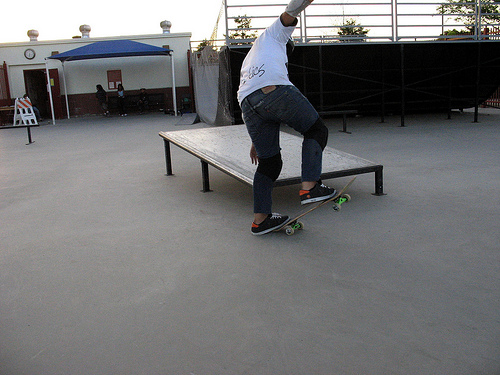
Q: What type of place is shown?
A: It is a park.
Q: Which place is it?
A: It is a park.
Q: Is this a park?
A: Yes, it is a park.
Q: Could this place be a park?
A: Yes, it is a park.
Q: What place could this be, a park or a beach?
A: It is a park.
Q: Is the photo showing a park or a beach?
A: It is showing a park.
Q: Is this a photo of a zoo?
A: No, the picture is showing a park.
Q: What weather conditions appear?
A: It is cloudy.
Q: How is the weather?
A: It is cloudy.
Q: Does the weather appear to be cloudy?
A: Yes, it is cloudy.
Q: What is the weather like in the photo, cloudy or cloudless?
A: It is cloudy.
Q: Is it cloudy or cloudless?
A: It is cloudy.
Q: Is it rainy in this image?
A: No, it is cloudy.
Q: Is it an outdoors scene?
A: Yes, it is outdoors.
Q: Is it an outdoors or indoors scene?
A: It is outdoors.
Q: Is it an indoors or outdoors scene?
A: It is outdoors.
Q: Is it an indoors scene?
A: No, it is outdoors.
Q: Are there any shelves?
A: No, there are no shelves.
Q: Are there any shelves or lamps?
A: No, there are no shelves or lamps.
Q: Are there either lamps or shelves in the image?
A: No, there are no shelves or lamps.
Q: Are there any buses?
A: No, there are no buses.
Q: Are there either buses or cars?
A: No, there are no buses or cars.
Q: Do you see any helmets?
A: No, there are no helmets.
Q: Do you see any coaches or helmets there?
A: No, there are no helmets or coaches.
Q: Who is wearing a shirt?
A: The man is wearing a shirt.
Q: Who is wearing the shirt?
A: The man is wearing a shirt.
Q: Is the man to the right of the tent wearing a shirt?
A: Yes, the man is wearing a shirt.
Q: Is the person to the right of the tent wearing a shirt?
A: Yes, the man is wearing a shirt.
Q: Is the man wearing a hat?
A: No, the man is wearing a shirt.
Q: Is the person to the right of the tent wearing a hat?
A: No, the man is wearing a shirt.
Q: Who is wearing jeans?
A: The man is wearing jeans.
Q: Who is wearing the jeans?
A: The man is wearing jeans.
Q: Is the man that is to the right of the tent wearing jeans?
A: Yes, the man is wearing jeans.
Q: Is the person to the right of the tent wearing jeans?
A: Yes, the man is wearing jeans.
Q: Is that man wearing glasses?
A: No, the man is wearing jeans.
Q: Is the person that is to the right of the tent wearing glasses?
A: No, the man is wearing jeans.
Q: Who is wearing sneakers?
A: The man is wearing sneakers.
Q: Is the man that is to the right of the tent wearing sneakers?
A: Yes, the man is wearing sneakers.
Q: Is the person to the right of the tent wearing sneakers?
A: Yes, the man is wearing sneakers.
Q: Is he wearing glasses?
A: No, the man is wearing sneakers.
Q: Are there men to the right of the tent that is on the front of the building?
A: Yes, there is a man to the right of the tent.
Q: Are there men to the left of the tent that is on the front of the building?
A: No, the man is to the right of the tent.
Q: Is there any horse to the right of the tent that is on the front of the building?
A: No, there is a man to the right of the tent.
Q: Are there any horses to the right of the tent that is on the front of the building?
A: No, there is a man to the right of the tent.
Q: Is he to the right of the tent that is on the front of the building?
A: Yes, the man is to the right of the tent.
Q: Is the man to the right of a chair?
A: No, the man is to the right of the tent.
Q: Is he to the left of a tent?
A: No, the man is to the right of a tent.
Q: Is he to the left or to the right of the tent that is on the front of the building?
A: The man is to the right of the tent.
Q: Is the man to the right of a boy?
A: No, the man is to the right of the tent.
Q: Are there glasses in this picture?
A: No, there are no glasses.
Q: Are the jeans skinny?
A: Yes, the jeans are skinny.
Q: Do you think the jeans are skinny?
A: Yes, the jeans are skinny.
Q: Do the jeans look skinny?
A: Yes, the jeans are skinny.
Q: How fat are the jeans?
A: The jeans are skinny.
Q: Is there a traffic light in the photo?
A: No, there are no traffic lights.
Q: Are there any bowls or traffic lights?
A: No, there are no traffic lights or bowls.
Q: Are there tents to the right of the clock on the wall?
A: Yes, there is a tent to the right of the clock.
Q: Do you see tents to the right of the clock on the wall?
A: Yes, there is a tent to the right of the clock.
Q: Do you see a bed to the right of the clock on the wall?
A: No, there is a tent to the right of the clock.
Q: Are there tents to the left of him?
A: Yes, there is a tent to the left of the man.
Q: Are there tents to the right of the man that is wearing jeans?
A: No, the tent is to the left of the man.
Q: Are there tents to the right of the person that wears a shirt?
A: No, the tent is to the left of the man.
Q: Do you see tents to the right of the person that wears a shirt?
A: No, the tent is to the left of the man.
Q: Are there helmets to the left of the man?
A: No, there is a tent to the left of the man.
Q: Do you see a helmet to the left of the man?
A: No, there is a tent to the left of the man.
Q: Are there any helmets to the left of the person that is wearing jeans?
A: No, there is a tent to the left of the man.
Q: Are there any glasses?
A: No, there are no glasses.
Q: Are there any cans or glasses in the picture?
A: No, there are no glasses or cans.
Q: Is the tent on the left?
A: Yes, the tent is on the left of the image.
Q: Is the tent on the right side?
A: No, the tent is on the left of the image.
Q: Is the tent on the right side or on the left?
A: The tent is on the left of the image.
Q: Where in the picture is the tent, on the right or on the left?
A: The tent is on the left of the image.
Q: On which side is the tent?
A: The tent is on the left of the image.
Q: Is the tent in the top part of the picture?
A: Yes, the tent is in the top of the image.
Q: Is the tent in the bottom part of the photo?
A: No, the tent is in the top of the image.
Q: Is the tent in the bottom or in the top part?
A: The tent is in the top of the image.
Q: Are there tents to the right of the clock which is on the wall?
A: Yes, there is a tent to the right of the clock.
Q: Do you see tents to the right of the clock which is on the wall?
A: Yes, there is a tent to the right of the clock.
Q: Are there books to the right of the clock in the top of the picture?
A: No, there is a tent to the right of the clock.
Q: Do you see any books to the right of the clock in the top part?
A: No, there is a tent to the right of the clock.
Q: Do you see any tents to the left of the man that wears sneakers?
A: Yes, there is a tent to the left of the man.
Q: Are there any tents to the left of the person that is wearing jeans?
A: Yes, there is a tent to the left of the man.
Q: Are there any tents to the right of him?
A: No, the tent is to the left of the man.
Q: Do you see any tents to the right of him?
A: No, the tent is to the left of the man.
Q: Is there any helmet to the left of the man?
A: No, there is a tent to the left of the man.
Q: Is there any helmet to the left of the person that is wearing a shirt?
A: No, there is a tent to the left of the man.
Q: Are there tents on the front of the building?
A: Yes, there is a tent on the front of the building.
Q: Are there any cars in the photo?
A: No, there are no cars.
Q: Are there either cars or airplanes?
A: No, there are no cars or airplanes.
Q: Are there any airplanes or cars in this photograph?
A: No, there are no cars or airplanes.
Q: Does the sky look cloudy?
A: Yes, the sky is cloudy.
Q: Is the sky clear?
A: No, the sky is cloudy.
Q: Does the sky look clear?
A: No, the sky is cloudy.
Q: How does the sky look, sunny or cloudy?
A: The sky is cloudy.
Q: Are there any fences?
A: Yes, there is a fence.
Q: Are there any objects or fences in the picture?
A: Yes, there is a fence.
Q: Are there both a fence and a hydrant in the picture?
A: No, there is a fence but no fire hydrants.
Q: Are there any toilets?
A: No, there are no toilets.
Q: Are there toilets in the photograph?
A: No, there are no toilets.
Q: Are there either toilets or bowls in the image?
A: No, there are no toilets or bowls.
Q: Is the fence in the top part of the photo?
A: Yes, the fence is in the top of the image.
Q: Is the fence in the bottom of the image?
A: No, the fence is in the top of the image.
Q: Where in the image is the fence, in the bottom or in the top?
A: The fence is in the top of the image.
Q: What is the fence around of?
A: The fence is around the park.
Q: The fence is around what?
A: The fence is around the park.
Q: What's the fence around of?
A: The fence is around the park.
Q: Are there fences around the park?
A: Yes, there is a fence around the park.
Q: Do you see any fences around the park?
A: Yes, there is a fence around the park.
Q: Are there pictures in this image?
A: No, there are no pictures.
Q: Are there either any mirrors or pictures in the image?
A: No, there are no pictures or mirrors.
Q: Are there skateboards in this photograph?
A: Yes, there is a skateboard.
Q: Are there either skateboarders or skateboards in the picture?
A: Yes, there is a skateboard.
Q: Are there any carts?
A: No, there are no carts.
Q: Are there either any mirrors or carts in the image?
A: No, there are no carts or mirrors.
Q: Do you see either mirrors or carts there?
A: No, there are no carts or mirrors.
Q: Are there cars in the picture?
A: No, there are no cars.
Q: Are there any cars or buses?
A: No, there are no cars or buses.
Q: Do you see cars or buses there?
A: No, there are no cars or buses.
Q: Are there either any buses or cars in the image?
A: No, there are no cars or buses.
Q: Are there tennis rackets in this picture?
A: No, there are no tennis rackets.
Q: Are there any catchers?
A: No, there are no catchers.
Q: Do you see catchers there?
A: No, there are no catchers.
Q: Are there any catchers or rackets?
A: No, there are no catchers or rackets.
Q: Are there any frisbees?
A: No, there are no frisbees.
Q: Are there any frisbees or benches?
A: No, there are no frisbees or benches.